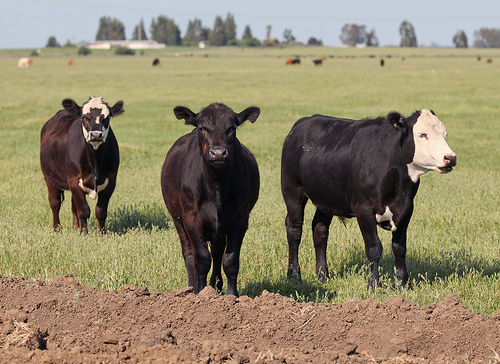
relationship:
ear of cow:
[173, 103, 198, 127] [159, 101, 262, 298]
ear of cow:
[236, 105, 263, 126] [159, 101, 262, 298]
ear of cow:
[60, 97, 83, 117] [38, 98, 127, 236]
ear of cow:
[109, 97, 127, 116] [38, 98, 127, 236]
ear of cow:
[385, 111, 407, 134] [280, 107, 457, 293]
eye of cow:
[198, 127, 206, 136] [159, 101, 262, 298]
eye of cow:
[226, 126, 237, 135] [159, 101, 262, 298]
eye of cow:
[418, 133, 429, 141] [280, 107, 457, 293]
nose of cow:
[89, 131, 106, 142] [38, 98, 127, 236]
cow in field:
[38, 98, 127, 236] [0, 61, 499, 319]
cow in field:
[159, 101, 262, 298] [0, 61, 499, 319]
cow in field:
[280, 107, 457, 293] [0, 61, 499, 319]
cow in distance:
[150, 56, 162, 67] [0, 18, 499, 76]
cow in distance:
[17, 57, 32, 67] [0, 18, 499, 76]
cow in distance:
[285, 55, 303, 67] [0, 18, 499, 76]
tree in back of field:
[208, 15, 229, 47] [0, 61, 499, 319]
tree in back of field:
[223, 11, 236, 45] [0, 61, 499, 319]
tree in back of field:
[340, 23, 367, 47] [0, 61, 499, 319]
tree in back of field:
[397, 19, 417, 49] [0, 61, 499, 319]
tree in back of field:
[450, 29, 470, 50] [0, 61, 499, 319]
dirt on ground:
[2, 272, 497, 363] [2, 243, 498, 364]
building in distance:
[80, 38, 166, 51] [0, 18, 499, 76]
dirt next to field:
[2, 272, 497, 363] [0, 61, 499, 319]